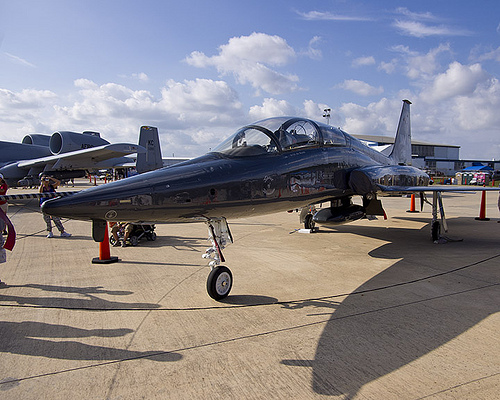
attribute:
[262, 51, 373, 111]
sky — pictured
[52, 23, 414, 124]
sky — blue, cloudless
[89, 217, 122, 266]
cone — orange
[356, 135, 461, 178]
building — white